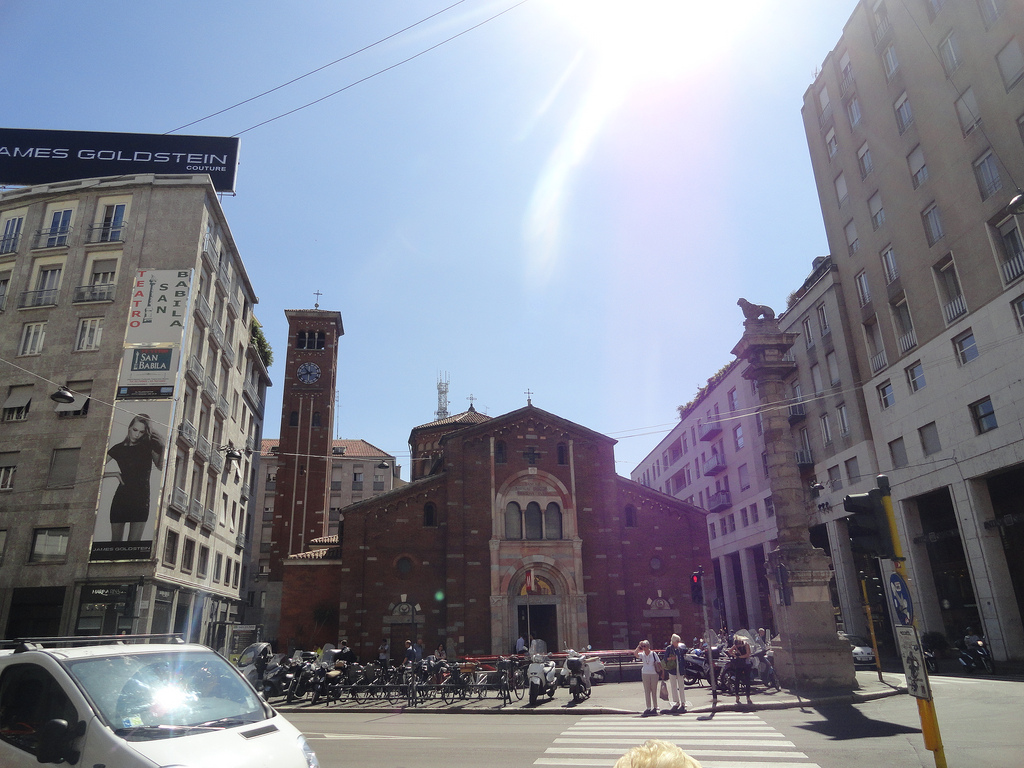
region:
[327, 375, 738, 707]
building on a city street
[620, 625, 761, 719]
people about to walk across street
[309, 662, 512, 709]
bikes parked on a sidewalk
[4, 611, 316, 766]
car on the road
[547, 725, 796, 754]
white painted lines on a walkway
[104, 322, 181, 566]
advertisement on a building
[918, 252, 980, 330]
window on a building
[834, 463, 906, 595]
traffic lights on a pole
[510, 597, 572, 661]
doorway to a building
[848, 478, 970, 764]
Yellow street sign on the side of the road.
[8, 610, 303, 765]
White car parked on the side of the road.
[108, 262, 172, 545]
Poster with a woman on the side of it.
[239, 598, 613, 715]
Group of motorcycles on the side of the road.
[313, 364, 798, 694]
Large church like building on the corner.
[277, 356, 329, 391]
Large clock on the side of the building.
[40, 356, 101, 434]
Open window on the side of the building.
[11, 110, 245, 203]
Black and white billboard sign above the building.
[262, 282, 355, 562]
a tower color red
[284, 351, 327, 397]
the clock on a tower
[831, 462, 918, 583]
traffic light on a pole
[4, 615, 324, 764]
a car is white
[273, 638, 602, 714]
bikes park on a rack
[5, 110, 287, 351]
a advertisement on the building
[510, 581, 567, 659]
the door is big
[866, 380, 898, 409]
a window on a building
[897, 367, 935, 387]
a window on a building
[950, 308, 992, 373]
a window on a building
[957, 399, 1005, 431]
a window on a building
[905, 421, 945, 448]
a window on a building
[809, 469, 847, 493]
a window on a building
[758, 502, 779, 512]
a window on a building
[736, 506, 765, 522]
a window on a building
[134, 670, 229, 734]
light is gleaming off the windshield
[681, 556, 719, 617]
traffic light is shining red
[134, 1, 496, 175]
power lines are running in the sky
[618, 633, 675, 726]
person is standing on the corner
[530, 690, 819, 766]
white lines of the crosswalk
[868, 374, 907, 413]
window is on the side of the building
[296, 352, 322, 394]
clock is on the tower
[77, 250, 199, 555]
advertisement is on the side of the building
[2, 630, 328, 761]
car is driving on the road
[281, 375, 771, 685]
Church on the corner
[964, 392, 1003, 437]
A window on a building.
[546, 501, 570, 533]
A window on a building.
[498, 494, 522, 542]
A window on a building.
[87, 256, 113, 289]
A window on a building.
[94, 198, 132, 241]
A window on a building.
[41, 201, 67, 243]
A window on a building.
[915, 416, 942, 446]
A window on a building.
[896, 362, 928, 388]
A window on a building.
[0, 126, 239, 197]
a sign on top of the building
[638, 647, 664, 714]
a person in a white shirt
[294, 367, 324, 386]
a clock on the building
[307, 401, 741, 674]
a brick building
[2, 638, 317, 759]
a white car on the street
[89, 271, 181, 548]
a white sign on the building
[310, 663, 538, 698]
bicycles on the sidewalk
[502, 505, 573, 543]
windows on the building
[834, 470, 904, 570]
black traffic light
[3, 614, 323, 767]
white vehicle in street